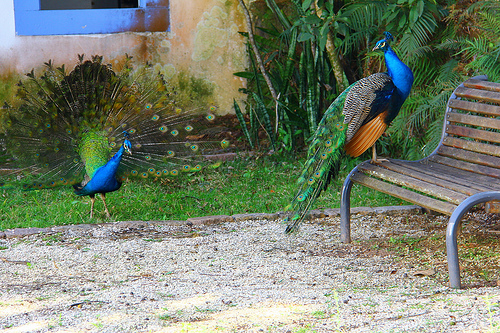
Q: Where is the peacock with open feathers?
A: On the ground.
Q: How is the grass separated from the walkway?
A: By a stone divider.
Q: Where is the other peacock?
A: On the bench.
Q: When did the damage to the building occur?
A: During a storm.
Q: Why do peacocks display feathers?
A: To attract mates.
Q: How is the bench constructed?
A: From wood and metal.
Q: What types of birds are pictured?
A: Peacocks.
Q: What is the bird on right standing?
A: Bench.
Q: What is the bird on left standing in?
A: Grass.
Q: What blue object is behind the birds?
A: Window.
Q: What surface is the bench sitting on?
A: Sand.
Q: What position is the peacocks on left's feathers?
A: Extended.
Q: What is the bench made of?
A: Metal and wood.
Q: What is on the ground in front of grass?
A: Pebbles.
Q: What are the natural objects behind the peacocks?
A: Plants.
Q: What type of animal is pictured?
A: Peacocks.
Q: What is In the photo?
A: A peacock.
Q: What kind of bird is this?
A: A peacock.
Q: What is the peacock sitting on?
A: A bench.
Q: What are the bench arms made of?
A: Metal.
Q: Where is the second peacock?
A: On the ground.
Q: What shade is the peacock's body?
A: Blue.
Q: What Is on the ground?
A: Gravel.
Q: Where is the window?
A: Behind the second peacock.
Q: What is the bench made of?
A: Wood and metal.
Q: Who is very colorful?
A: The peacocks.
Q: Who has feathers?
A: Peacocks.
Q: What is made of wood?
A: The bench.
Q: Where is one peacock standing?
A: On the bench.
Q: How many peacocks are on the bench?
A: One.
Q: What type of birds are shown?
A: Peacocks.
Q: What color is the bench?
A: Brown and gray.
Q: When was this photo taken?
A: During the daytime.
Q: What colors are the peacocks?
A: Blue, green and brown.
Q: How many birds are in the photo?
A: Two.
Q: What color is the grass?
A: Green.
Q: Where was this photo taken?
A: At a backyard.